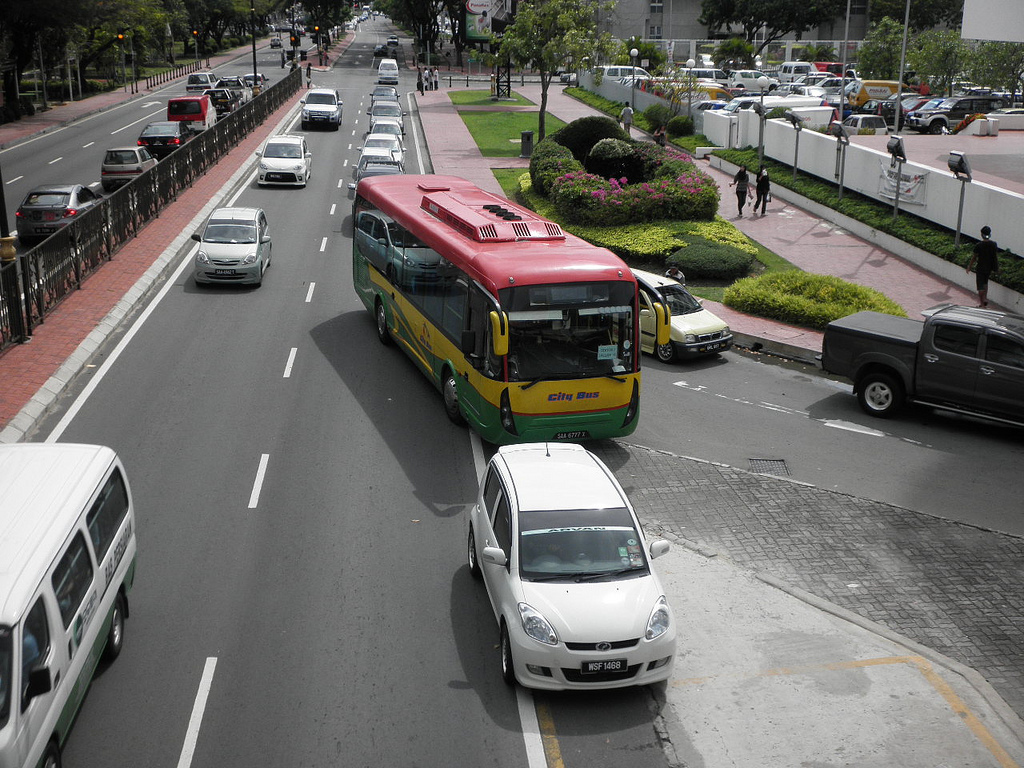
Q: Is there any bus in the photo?
A: Yes, there is a bus.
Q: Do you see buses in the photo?
A: Yes, there is a bus.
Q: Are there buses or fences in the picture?
A: Yes, there is a bus.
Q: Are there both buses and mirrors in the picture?
A: Yes, there are both a bus and a mirror.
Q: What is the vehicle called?
A: The vehicle is a bus.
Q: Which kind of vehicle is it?
A: The vehicle is a bus.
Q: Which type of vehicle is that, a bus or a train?
A: This is a bus.